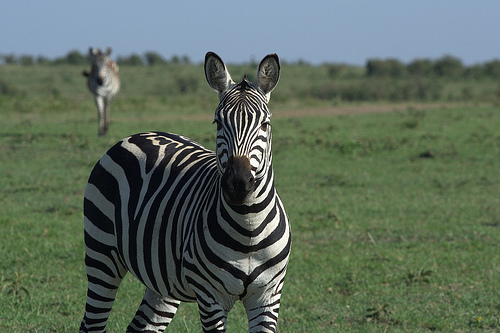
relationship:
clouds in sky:
[0, 0, 500, 63] [281, 12, 363, 50]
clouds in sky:
[213, 24, 285, 41] [1, 0, 499, 65]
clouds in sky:
[0, 0, 500, 63] [1, 3, 487, 60]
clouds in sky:
[0, 0, 500, 63] [2, 1, 499, 56]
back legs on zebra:
[73, 255, 191, 331] [26, 53, 338, 331]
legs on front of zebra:
[196, 291, 285, 331] [76, 44, 302, 331]